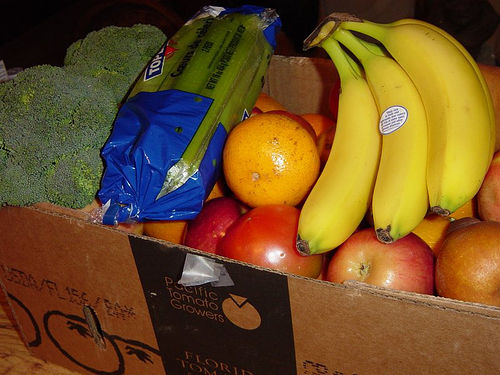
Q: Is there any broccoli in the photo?
A: Yes, there is broccoli.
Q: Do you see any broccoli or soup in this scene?
A: Yes, there is broccoli.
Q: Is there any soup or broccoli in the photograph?
A: Yes, there is broccoli.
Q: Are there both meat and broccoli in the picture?
A: No, there is broccoli but no meat.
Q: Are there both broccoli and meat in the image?
A: No, there is broccoli but no meat.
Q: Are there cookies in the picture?
A: No, there are no cookies.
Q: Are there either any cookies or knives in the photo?
A: No, there are no cookies or knives.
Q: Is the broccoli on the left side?
A: Yes, the broccoli is on the left of the image.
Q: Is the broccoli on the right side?
A: No, the broccoli is on the left of the image.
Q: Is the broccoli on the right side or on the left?
A: The broccoli is on the left of the image.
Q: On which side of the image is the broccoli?
A: The broccoli is on the left of the image.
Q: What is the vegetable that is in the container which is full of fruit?
A: The vegetable is broccoli.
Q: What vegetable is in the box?
A: The vegetable is broccoli.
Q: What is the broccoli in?
A: The broccoli is in the box.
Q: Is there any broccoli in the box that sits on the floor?
A: Yes, there is broccoli in the box.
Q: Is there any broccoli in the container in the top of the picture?
A: Yes, there is broccoli in the box.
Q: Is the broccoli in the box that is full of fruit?
A: Yes, the broccoli is in the box.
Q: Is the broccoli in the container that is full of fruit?
A: Yes, the broccoli is in the box.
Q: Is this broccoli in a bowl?
A: No, the broccoli is in the box.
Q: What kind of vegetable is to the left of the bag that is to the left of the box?
A: The vegetable is broccoli.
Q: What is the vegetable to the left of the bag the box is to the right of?
A: The vegetable is broccoli.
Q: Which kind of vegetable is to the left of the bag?
A: The vegetable is broccoli.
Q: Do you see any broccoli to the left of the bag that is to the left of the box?
A: Yes, there is broccoli to the left of the bag.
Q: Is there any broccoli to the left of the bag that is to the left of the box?
A: Yes, there is broccoli to the left of the bag.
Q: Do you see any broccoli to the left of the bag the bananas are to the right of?
A: Yes, there is broccoli to the left of the bag.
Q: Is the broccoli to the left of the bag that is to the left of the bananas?
A: Yes, the broccoli is to the left of the bag.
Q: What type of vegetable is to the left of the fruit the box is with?
A: The vegetable is broccoli.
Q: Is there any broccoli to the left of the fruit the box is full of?
A: Yes, there is broccoli to the left of the fruit.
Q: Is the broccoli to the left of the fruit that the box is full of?
A: Yes, the broccoli is to the left of the fruit.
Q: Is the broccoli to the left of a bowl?
A: No, the broccoli is to the left of the fruit.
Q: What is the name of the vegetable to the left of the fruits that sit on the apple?
A: The vegetable is broccoli.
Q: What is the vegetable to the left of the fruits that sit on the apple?
A: The vegetable is broccoli.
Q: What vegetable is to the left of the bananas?
A: The vegetable is broccoli.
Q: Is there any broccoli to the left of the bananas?
A: Yes, there is broccoli to the left of the bananas.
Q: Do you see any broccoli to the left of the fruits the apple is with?
A: Yes, there is broccoli to the left of the bananas.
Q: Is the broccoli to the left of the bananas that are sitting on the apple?
A: Yes, the broccoli is to the left of the bananas.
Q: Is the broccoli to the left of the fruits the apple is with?
A: Yes, the broccoli is to the left of the bananas.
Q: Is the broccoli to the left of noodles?
A: No, the broccoli is to the left of the bananas.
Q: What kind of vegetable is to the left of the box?
A: The vegetable is broccoli.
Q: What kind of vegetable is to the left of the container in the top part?
A: The vegetable is broccoli.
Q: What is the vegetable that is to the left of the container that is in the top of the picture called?
A: The vegetable is broccoli.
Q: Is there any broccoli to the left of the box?
A: Yes, there is broccoli to the left of the box.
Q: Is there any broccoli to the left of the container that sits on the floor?
A: Yes, there is broccoli to the left of the box.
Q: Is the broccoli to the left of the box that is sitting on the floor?
A: Yes, the broccoli is to the left of the box.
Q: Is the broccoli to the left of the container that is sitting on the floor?
A: Yes, the broccoli is to the left of the box.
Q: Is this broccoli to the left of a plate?
A: No, the broccoli is to the left of the box.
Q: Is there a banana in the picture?
A: Yes, there are bananas.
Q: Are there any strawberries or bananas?
A: Yes, there are bananas.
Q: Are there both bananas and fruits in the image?
A: Yes, there are both bananas and a fruit.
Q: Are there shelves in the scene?
A: No, there are no shelves.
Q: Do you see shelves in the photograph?
A: No, there are no shelves.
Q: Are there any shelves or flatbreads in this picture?
A: No, there are no shelves or flatbreads.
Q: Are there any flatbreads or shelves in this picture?
A: No, there are no shelves or flatbreads.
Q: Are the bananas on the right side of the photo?
A: Yes, the bananas are on the right of the image.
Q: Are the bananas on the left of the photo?
A: No, the bananas are on the right of the image.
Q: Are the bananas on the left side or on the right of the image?
A: The bananas are on the right of the image.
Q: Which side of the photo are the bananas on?
A: The bananas are on the right of the image.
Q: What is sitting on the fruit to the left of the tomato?
A: The bananas are sitting on the apple.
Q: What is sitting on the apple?
A: The bananas are sitting on the apple.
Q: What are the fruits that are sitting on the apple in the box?
A: The fruits are bananas.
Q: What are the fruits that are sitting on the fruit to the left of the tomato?
A: The fruits are bananas.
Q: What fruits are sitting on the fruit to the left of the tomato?
A: The fruits are bananas.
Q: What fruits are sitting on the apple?
A: The fruits are bananas.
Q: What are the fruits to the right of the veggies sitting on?
A: The bananas are sitting on the apple.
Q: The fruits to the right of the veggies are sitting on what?
A: The bananas are sitting on the apple.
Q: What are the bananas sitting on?
A: The bananas are sitting on the apple.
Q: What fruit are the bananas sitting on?
A: The bananas are sitting on the apple.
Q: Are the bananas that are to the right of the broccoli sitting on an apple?
A: Yes, the bananas are sitting on an apple.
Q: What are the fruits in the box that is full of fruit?
A: The fruits are bananas.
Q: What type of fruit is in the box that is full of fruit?
A: The fruits are bananas.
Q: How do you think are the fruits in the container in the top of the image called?
A: The fruits are bananas.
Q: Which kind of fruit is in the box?
A: The fruits are bananas.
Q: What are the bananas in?
A: The bananas are in the box.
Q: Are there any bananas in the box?
A: Yes, there are bananas in the box.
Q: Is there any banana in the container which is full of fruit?
A: Yes, there are bananas in the box.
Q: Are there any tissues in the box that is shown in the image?
A: No, there are bananas in the box.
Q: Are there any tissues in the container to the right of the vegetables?
A: No, there are bananas in the box.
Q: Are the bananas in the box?
A: Yes, the bananas are in the box.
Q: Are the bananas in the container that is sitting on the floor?
A: Yes, the bananas are in the box.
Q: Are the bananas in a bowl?
A: No, the bananas are in the box.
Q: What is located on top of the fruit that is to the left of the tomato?
A: The bananas are on top of the apple.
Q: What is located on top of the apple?
A: The bananas are on top of the apple.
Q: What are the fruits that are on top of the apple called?
A: The fruits are bananas.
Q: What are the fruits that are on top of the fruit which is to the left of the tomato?
A: The fruits are bananas.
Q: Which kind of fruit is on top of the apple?
A: The fruits are bananas.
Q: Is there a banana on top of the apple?
A: Yes, there are bananas on top of the apple.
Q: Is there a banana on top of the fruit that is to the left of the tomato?
A: Yes, there are bananas on top of the apple.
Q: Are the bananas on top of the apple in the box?
A: Yes, the bananas are on top of the apple.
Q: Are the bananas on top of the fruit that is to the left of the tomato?
A: Yes, the bananas are on top of the apple.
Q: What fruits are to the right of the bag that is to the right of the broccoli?
A: The fruits are bananas.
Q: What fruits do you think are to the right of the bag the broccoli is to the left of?
A: The fruits are bananas.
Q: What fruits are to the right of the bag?
A: The fruits are bananas.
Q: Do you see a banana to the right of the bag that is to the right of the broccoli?
A: Yes, there are bananas to the right of the bag.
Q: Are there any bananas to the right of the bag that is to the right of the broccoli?
A: Yes, there are bananas to the right of the bag.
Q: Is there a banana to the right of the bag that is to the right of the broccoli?
A: Yes, there are bananas to the right of the bag.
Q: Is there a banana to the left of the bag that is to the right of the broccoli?
A: No, the bananas are to the right of the bag.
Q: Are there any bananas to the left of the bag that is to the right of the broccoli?
A: No, the bananas are to the right of the bag.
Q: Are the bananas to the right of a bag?
A: Yes, the bananas are to the right of a bag.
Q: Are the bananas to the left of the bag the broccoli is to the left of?
A: No, the bananas are to the right of the bag.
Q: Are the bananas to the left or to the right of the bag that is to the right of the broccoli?
A: The bananas are to the right of the bag.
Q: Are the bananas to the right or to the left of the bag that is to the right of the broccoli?
A: The bananas are to the right of the bag.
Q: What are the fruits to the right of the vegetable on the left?
A: The fruits are bananas.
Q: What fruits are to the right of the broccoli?
A: The fruits are bananas.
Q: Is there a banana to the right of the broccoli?
A: Yes, there are bananas to the right of the broccoli.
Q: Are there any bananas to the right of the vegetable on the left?
A: Yes, there are bananas to the right of the broccoli.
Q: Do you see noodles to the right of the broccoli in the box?
A: No, there are bananas to the right of the broccoli.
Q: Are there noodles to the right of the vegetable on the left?
A: No, there are bananas to the right of the broccoli.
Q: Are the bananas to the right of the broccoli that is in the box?
A: Yes, the bananas are to the right of the broccoli.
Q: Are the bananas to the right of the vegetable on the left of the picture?
A: Yes, the bananas are to the right of the broccoli.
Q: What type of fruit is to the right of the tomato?
A: The fruits are bananas.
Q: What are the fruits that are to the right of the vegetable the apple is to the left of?
A: The fruits are bananas.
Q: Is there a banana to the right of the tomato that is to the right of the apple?
A: Yes, there are bananas to the right of the tomato.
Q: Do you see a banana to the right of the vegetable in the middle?
A: Yes, there are bananas to the right of the tomato.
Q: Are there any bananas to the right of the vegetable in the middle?
A: Yes, there are bananas to the right of the tomato.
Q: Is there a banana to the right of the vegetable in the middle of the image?
A: Yes, there are bananas to the right of the tomato.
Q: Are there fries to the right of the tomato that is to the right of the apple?
A: No, there are bananas to the right of the tomato.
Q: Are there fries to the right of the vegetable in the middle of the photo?
A: No, there are bananas to the right of the tomato.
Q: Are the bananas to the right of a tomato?
A: Yes, the bananas are to the right of a tomato.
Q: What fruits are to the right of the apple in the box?
A: The fruits are bananas.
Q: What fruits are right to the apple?
A: The fruits are bananas.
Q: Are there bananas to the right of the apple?
A: Yes, there are bananas to the right of the apple.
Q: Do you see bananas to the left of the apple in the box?
A: No, the bananas are to the right of the apple.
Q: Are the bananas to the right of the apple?
A: Yes, the bananas are to the right of the apple.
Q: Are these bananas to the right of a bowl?
A: No, the bananas are to the right of the apple.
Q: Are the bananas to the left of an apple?
A: No, the bananas are to the right of an apple.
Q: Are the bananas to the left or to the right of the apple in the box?
A: The bananas are to the right of the apple.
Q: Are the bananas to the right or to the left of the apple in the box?
A: The bananas are to the right of the apple.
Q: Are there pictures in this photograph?
A: No, there are no pictures.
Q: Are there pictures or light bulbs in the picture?
A: No, there are no pictures or light bulbs.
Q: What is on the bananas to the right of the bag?
A: The stickers are on the bananas.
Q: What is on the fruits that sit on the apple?
A: The stickers are on the bananas.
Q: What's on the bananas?
A: The stickers are on the bananas.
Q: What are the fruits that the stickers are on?
A: The fruits are bananas.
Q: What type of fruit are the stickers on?
A: The stickers are on the bananas.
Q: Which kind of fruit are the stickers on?
A: The stickers are on the bananas.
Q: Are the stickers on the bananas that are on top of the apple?
A: Yes, the stickers are on the bananas.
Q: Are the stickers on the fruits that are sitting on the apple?
A: Yes, the stickers are on the bananas.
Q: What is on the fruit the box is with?
A: The stickers are on the fruit.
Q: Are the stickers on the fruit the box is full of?
A: Yes, the stickers are on the fruit.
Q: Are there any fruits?
A: Yes, there is a fruit.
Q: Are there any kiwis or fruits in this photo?
A: Yes, there is a fruit.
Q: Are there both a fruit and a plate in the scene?
A: No, there is a fruit but no plates.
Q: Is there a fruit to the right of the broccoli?
A: Yes, there is a fruit to the right of the broccoli.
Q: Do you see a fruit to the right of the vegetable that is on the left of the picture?
A: Yes, there is a fruit to the right of the broccoli.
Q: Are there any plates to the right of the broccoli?
A: No, there is a fruit to the right of the broccoli.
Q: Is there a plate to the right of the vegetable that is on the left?
A: No, there is a fruit to the right of the broccoli.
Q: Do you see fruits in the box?
A: Yes, there is a fruit in the box.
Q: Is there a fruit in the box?
A: Yes, there is a fruit in the box.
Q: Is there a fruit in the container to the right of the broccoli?
A: Yes, there is a fruit in the box.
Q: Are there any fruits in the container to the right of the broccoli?
A: Yes, there is a fruit in the box.